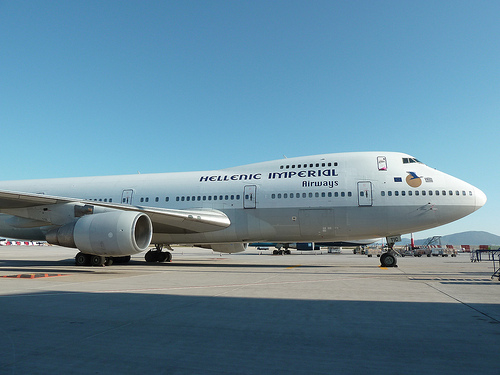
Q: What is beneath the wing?
A: Jet engine.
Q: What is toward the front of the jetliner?
A: Cockpit.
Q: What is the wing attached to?
A: A large jet.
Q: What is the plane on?
A: A hanger.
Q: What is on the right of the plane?
A: A wing.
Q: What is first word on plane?
A: Hellenic.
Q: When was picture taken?
A: Daytime.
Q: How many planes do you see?
A: One.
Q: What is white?
A: A plane.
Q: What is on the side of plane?
A: Windows.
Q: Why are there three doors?
A: Entering and exiting.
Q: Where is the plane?
A: Airport.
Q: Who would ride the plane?
A: Passengers.